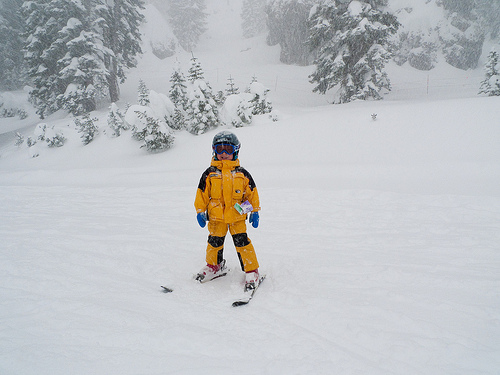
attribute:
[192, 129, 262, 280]
boy — wearing skis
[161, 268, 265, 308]
boy's skis — white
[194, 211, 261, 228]
boy's gloves — blue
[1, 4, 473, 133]
trees — behind the boy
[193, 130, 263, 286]
small boy — skiing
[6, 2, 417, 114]
small trees — Snow covered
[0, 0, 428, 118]
evergreen — snow covered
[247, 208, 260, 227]
blue mitten — boy's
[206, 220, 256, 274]
snow pants — yellow and black, boy's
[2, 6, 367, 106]
trees — a grouping, snowy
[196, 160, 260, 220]
jacket — yellow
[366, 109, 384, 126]
object — small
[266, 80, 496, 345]
snow — white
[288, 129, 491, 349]
snow — white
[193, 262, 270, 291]
shoes — boy's, white, small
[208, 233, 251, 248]
knee pads — black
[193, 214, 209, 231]
glove — small, blue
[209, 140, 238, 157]
goggles — dark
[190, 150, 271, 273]
snow suit — yellow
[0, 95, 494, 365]
field — snowy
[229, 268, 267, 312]
snow ski — child-sized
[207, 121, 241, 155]
ski helmet — child-sized, blue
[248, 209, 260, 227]
mitten — blue, child's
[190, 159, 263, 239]
coat — child's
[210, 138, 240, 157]
ski goggles — blue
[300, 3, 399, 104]
tree — snow-covered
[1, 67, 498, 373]
snow — powdery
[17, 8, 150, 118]
evergreen — large, snow covered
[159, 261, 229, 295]
skis — small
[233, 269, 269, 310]
skis — small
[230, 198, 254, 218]
ticket — ski lift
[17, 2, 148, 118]
trees — snow covered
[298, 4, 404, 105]
trees — snow covered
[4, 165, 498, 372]
tracks — ski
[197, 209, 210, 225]
gloves — blue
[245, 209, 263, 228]
gloves — blue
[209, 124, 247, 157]
helmet — green, ski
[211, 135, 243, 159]
goggles — blue, ski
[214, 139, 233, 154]
lenses — orange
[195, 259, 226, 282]
boots — red, ski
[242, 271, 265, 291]
boots — red, ski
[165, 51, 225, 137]
saplings — snow covered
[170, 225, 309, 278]
pants — yellow 